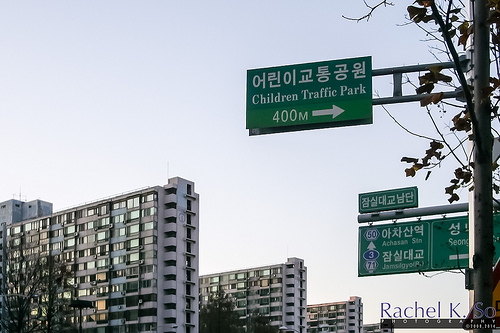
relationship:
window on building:
[123, 222, 146, 241] [4, 170, 205, 330]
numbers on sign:
[367, 231, 376, 239] [357, 221, 429, 273]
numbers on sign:
[370, 223, 378, 240] [357, 221, 429, 273]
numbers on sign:
[364, 247, 377, 260] [357, 221, 429, 273]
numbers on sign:
[368, 261, 378, 268] [357, 221, 429, 273]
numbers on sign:
[369, 256, 378, 271] [357, 221, 429, 273]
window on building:
[141, 207, 155, 219] [4, 170, 205, 330]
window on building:
[117, 203, 158, 226] [95, 162, 215, 320]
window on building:
[98, 257, 110, 264] [4, 170, 205, 330]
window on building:
[135, 194, 161, 208] [0, 171, 220, 324]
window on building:
[125, 196, 143, 211] [4, 170, 205, 330]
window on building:
[128, 206, 142, 218] [4, 170, 205, 330]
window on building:
[127, 220, 140, 232] [4, 170, 205, 330]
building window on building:
[124, 247, 141, 263] [0, 163, 244, 333]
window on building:
[97, 217, 110, 228] [4, 170, 205, 330]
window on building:
[123, 282, 140, 290] [4, 170, 205, 330]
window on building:
[256, 268, 270, 275] [198, 256, 305, 330]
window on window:
[325, 313, 335, 317] [123, 282, 140, 290]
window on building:
[120, 201, 145, 208] [10, 160, 198, 330]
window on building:
[128, 240, 143, 249] [1, 174, 245, 330]